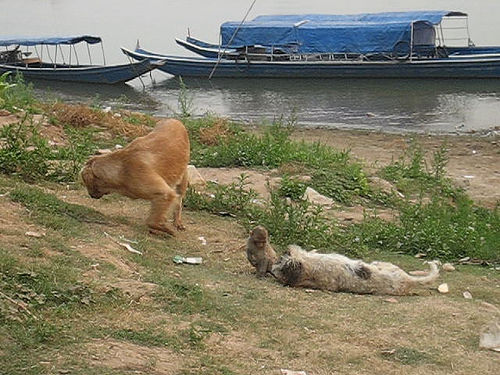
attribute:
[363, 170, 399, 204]
rock — large, lying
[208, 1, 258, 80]
anchor rope — used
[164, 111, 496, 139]
water shoreline — large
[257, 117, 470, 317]
monkey — small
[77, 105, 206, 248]
yellow dog — big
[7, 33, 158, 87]
boat — large, fishing, smaller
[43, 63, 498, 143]
body of water — large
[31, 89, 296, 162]
patches of grass — tall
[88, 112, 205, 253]
dog — white, patchy, fluffy, golden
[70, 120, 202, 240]
dog — light, brown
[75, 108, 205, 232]
brown fur — patch